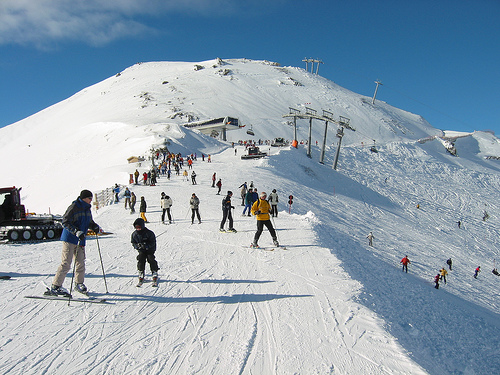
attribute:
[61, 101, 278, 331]
snow — thick, white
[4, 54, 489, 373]
mountain — large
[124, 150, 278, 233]
skiers — group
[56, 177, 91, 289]
man — skiing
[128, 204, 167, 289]
kid — skiing, little, learning to ski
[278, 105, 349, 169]
poles — ski lift, four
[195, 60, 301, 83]
rocks — grey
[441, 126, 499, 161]
hill — small, off to the side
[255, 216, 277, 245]
pants — black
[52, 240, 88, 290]
pants — white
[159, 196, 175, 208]
jacket — white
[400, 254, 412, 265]
jacket — red